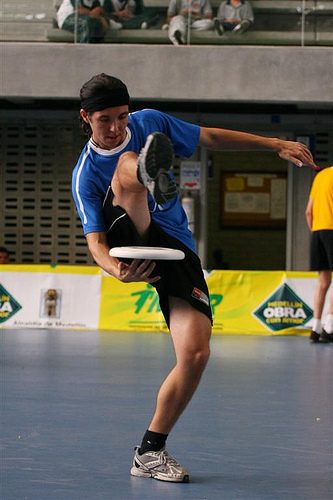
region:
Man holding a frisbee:
[98, 242, 186, 272]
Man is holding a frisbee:
[107, 241, 193, 265]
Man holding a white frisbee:
[101, 238, 193, 268]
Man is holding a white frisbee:
[102, 238, 197, 264]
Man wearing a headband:
[76, 87, 138, 115]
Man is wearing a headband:
[75, 85, 132, 113]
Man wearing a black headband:
[72, 86, 134, 114]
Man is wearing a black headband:
[80, 85, 132, 115]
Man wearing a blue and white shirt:
[67, 104, 203, 256]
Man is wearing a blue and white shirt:
[64, 103, 208, 257]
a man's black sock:
[137, 430, 166, 453]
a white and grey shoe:
[132, 446, 188, 481]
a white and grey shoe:
[136, 131, 178, 204]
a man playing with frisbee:
[71, 71, 319, 482]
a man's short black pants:
[97, 194, 210, 322]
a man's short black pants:
[307, 230, 331, 268]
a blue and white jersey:
[70, 111, 201, 254]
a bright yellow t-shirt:
[307, 165, 331, 231]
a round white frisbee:
[107, 245, 184, 260]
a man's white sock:
[311, 317, 320, 332]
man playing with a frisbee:
[57, 70, 319, 493]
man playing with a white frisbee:
[60, 45, 305, 483]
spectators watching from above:
[3, 0, 328, 45]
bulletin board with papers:
[221, 166, 302, 228]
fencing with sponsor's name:
[3, 263, 328, 338]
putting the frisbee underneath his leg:
[70, 72, 318, 476]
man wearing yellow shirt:
[303, 158, 331, 340]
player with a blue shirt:
[71, 87, 318, 498]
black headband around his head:
[75, 90, 138, 115]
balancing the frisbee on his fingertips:
[105, 246, 188, 286]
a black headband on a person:
[77, 90, 135, 110]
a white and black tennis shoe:
[123, 442, 191, 482]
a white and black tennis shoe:
[138, 124, 177, 206]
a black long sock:
[135, 426, 169, 453]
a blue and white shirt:
[66, 106, 206, 261]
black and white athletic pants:
[102, 194, 219, 326]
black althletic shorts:
[310, 220, 330, 275]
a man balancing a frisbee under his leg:
[63, 84, 241, 481]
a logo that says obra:
[257, 276, 312, 339]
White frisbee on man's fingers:
[109, 245, 187, 261]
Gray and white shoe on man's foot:
[133, 447, 188, 481]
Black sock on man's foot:
[138, 429, 169, 446]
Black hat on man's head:
[79, 73, 130, 102]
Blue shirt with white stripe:
[69, 104, 199, 253]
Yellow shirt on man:
[307, 164, 331, 232]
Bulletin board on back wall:
[222, 170, 286, 232]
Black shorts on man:
[109, 195, 215, 317]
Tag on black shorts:
[190, 284, 212, 303]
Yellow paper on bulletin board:
[227, 178, 244, 189]